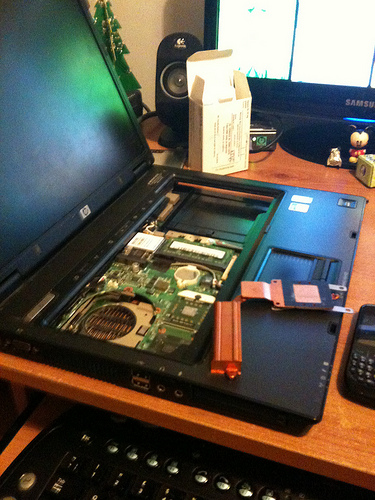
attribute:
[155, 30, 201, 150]
speaker — in the background, computer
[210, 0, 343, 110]
tv — samsung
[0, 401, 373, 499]
keyboard — black 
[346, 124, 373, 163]
mickey mouse — small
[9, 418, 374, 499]
keyboard — black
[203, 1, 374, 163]
tv — flat screen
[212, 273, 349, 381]
device — orange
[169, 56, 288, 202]
box — open, white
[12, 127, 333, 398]
notebook computer — broken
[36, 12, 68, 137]
computer screen — black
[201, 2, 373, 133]
computer monitor — samsung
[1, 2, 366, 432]
laptop — broken, missing keyboard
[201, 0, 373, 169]
computer — desktop